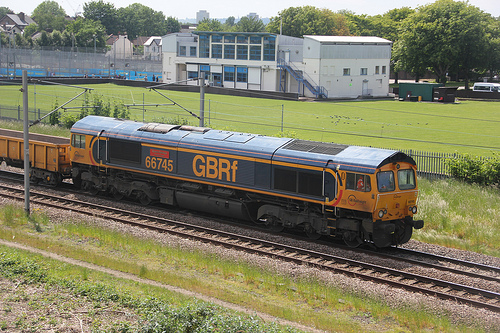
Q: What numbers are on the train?
A: 66745.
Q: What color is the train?
A: Navy and yellow.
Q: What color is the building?
A: White.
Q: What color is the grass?
A: Green.